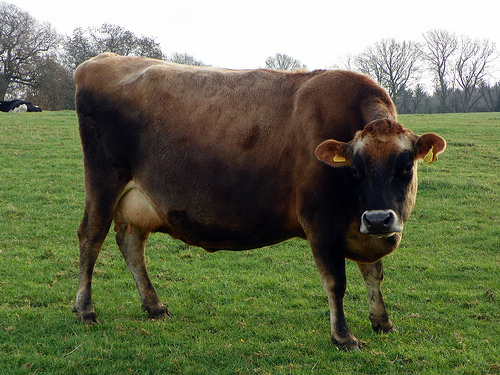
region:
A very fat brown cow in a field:
[61, 42, 446, 344]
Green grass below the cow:
[173, 254, 313, 359]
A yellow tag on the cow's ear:
[330, 150, 351, 165]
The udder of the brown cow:
[104, 184, 181, 236]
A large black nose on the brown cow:
[362, 207, 392, 239]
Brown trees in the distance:
[372, 31, 496, 116]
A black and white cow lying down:
[1, 95, 51, 115]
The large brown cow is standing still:
[58, 32, 449, 353]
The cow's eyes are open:
[348, 160, 421, 180]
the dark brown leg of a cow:
[73, 138, 122, 323]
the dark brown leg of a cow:
[115, 221, 167, 318]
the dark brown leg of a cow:
[308, 229, 359, 348]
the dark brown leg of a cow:
[361, 258, 394, 335]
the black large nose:
[365, 210, 393, 232]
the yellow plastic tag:
[332, 151, 344, 163]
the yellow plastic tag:
[422, 143, 435, 163]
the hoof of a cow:
[75, 308, 96, 324]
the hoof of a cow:
[142, 304, 170, 319]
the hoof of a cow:
[330, 336, 360, 352]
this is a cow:
[53, 33, 439, 359]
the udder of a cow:
[113, 190, 162, 245]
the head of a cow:
[307, 100, 462, 272]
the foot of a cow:
[293, 208, 365, 368]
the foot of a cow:
[361, 250, 413, 347]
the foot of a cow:
[112, 227, 185, 331]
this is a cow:
[0, 6, 36, 106]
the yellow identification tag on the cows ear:
[312, 140, 357, 170]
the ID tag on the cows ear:
[421, 145, 432, 165]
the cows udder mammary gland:
[112, 188, 159, 238]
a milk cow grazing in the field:
[70, 51, 445, 347]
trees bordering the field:
[401, 27, 499, 118]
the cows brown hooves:
[71, 298, 99, 325]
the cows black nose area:
[358, 209, 401, 239]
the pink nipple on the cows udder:
[124, 222, 134, 237]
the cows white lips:
[358, 209, 404, 238]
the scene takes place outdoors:
[1, 3, 493, 373]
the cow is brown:
[73, 52, 447, 330]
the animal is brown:
[71, 58, 450, 324]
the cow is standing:
[75, 56, 442, 348]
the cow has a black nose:
[358, 209, 398, 230]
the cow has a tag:
[331, 153, 347, 163]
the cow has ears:
[314, 133, 448, 162]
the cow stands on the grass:
[3, 52, 498, 372]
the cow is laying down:
[0, 100, 42, 112]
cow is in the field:
[72, 49, 448, 354]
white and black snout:
[351, 202, 416, 234]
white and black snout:
[351, 205, 418, 245]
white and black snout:
[357, 206, 411, 243]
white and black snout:
[355, 208, 422, 245]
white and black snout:
[357, 206, 415, 243]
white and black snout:
[350, 202, 406, 242]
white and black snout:
[358, 200, 408, 245]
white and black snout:
[347, 205, 417, 252]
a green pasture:
[4, 104, 490, 369]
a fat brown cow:
[64, 47, 458, 358]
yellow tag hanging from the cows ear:
[411, 128, 446, 170]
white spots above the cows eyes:
[345, 129, 425, 160]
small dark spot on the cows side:
[238, 120, 268, 155]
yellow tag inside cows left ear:
[319, 140, 351, 167]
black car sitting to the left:
[0, 94, 48, 116]